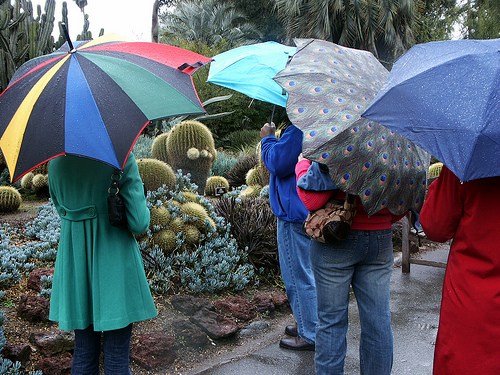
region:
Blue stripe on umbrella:
[61, 54, 98, 180]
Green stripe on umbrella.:
[133, 64, 170, 107]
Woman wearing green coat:
[52, 174, 108, 281]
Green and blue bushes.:
[159, 179, 244, 304]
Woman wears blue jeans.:
[69, 328, 144, 373]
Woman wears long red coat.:
[431, 166, 498, 373]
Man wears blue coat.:
[261, 124, 303, 227]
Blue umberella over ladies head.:
[376, 50, 496, 190]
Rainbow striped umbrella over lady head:
[2, 44, 183, 157]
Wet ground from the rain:
[204, 339, 278, 373]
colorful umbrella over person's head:
[10, 13, 201, 159]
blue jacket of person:
[43, 161, 141, 273]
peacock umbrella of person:
[296, 70, 382, 150]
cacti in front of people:
[171, 126, 225, 186]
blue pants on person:
[311, 249, 377, 312]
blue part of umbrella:
[51, 87, 103, 149]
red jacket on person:
[437, 194, 496, 307]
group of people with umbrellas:
[42, 71, 460, 251]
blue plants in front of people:
[177, 241, 236, 293]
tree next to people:
[317, 6, 378, 44]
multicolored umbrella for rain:
[73, 32, 225, 124]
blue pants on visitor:
[259, 208, 344, 345]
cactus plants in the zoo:
[136, 162, 218, 284]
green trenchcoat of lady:
[40, 202, 189, 322]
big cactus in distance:
[164, 110, 244, 181]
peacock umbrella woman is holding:
[286, 62, 408, 208]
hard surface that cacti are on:
[164, 295, 258, 347]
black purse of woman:
[100, 179, 168, 244]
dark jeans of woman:
[71, 331, 168, 364]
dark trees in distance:
[203, 95, 273, 154]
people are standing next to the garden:
[3, 5, 499, 366]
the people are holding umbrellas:
[6, 10, 497, 365]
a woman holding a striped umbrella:
[0, 19, 198, 374]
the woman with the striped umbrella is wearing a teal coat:
[3, 19, 205, 360]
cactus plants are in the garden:
[8, 118, 291, 238]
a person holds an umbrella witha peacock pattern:
[280, 32, 428, 372]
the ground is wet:
[191, 227, 499, 369]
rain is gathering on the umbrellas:
[7, 10, 488, 370]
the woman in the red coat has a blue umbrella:
[375, 20, 492, 370]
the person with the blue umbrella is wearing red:
[365, 32, 498, 371]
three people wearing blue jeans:
[38, 55, 397, 369]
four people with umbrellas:
[30, 40, 495, 374]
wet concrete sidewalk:
[397, 268, 435, 372]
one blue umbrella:
[363, 34, 498, 189]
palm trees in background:
[202, 4, 437, 40]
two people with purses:
[82, 147, 378, 269]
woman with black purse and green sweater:
[43, 151, 170, 372]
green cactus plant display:
[148, 125, 253, 259]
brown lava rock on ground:
[160, 293, 279, 350]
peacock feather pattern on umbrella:
[280, 27, 433, 220]